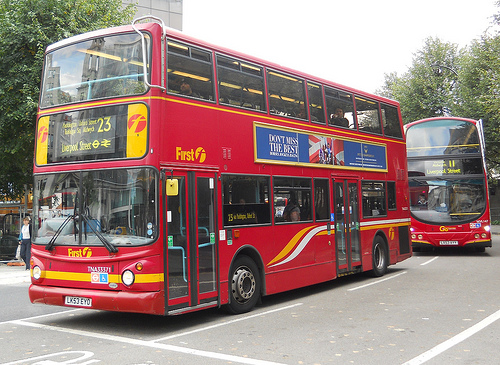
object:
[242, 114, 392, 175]
sign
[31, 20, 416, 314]
bus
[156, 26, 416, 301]
side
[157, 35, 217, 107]
window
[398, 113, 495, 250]
bus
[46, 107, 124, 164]
sign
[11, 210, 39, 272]
lady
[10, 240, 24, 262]
bag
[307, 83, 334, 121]
window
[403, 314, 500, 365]
line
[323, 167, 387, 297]
door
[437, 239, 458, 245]
licence plate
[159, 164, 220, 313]
door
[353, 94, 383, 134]
window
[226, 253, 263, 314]
tire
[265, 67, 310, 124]
window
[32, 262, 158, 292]
yellow line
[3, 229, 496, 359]
street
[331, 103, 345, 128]
passenger